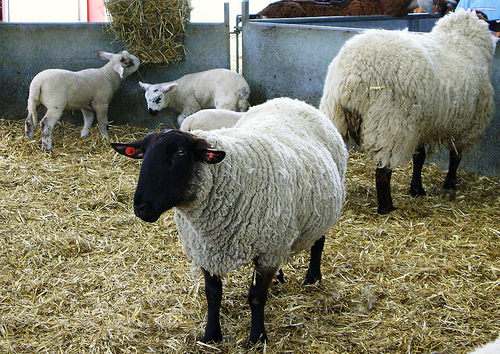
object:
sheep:
[319, 6, 494, 214]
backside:
[318, 29, 426, 112]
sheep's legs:
[201, 267, 223, 343]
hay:
[334, 226, 484, 351]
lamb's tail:
[28, 86, 41, 128]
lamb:
[25, 50, 141, 151]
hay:
[101, 0, 194, 68]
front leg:
[195, 270, 225, 346]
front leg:
[248, 256, 287, 343]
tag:
[125, 147, 135, 156]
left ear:
[199, 147, 226, 164]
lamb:
[108, 97, 349, 343]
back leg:
[302, 235, 325, 285]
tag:
[207, 152, 217, 158]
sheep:
[109, 97, 349, 349]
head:
[110, 130, 227, 223]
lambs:
[24, 50, 141, 151]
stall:
[0, 22, 500, 181]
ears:
[110, 143, 144, 159]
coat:
[174, 97, 349, 277]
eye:
[178, 149, 188, 156]